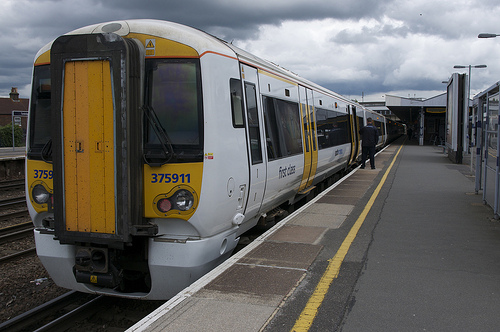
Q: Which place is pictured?
A: It is a station.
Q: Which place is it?
A: It is a station.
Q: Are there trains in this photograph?
A: Yes, there is a train.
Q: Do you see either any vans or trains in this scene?
A: Yes, there is a train.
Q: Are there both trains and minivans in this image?
A: No, there is a train but no minivans.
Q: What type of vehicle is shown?
A: The vehicle is a train.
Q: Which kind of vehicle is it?
A: The vehicle is a train.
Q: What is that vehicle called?
A: This is a train.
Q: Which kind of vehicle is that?
A: This is a train.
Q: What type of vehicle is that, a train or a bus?
A: This is a train.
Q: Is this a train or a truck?
A: This is a train.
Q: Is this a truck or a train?
A: This is a train.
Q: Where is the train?
A: The train is at the station.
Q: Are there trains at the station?
A: Yes, there is a train at the station.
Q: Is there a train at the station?
A: Yes, there is a train at the station.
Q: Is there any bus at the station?
A: No, there is a train at the station.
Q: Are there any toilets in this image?
A: No, there are no toilets.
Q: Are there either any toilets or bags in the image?
A: No, there are no toilets or bags.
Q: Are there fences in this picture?
A: No, there are no fences.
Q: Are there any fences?
A: No, there are no fences.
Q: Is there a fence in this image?
A: No, there are no fences.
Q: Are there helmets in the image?
A: No, there are no helmets.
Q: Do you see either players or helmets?
A: No, there are no helmets or players.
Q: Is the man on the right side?
A: Yes, the man is on the right of the image.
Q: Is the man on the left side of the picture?
A: No, the man is on the right of the image.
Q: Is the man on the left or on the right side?
A: The man is on the right of the image.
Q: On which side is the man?
A: The man is on the right of the image.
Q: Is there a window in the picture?
A: Yes, there is a window.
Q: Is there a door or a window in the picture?
A: Yes, there is a window.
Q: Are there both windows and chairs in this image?
A: No, there is a window but no chairs.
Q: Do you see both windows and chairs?
A: No, there is a window but no chairs.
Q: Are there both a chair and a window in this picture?
A: No, there is a window but no chairs.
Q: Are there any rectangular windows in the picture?
A: Yes, there is a rectangular window.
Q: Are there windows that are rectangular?
A: Yes, there is a window that is rectangular.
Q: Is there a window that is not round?
A: Yes, there is a rectangular window.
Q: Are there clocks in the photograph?
A: No, there are no clocks.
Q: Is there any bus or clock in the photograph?
A: No, there are no clocks or buses.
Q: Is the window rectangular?
A: Yes, the window is rectangular.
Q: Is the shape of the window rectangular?
A: Yes, the window is rectangular.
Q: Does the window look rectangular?
A: Yes, the window is rectangular.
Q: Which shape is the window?
A: The window is rectangular.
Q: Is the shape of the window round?
A: No, the window is rectangular.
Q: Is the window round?
A: No, the window is rectangular.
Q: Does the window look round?
A: No, the window is rectangular.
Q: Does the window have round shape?
A: No, the window is rectangular.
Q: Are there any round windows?
A: No, there is a window but it is rectangular.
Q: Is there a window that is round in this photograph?
A: No, there is a window but it is rectangular.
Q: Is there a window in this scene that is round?
A: No, there is a window but it is rectangular.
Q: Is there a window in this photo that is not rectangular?
A: No, there is a window but it is rectangular.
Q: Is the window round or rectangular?
A: The window is rectangular.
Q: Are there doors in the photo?
A: Yes, there is a door.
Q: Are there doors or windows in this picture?
A: Yes, there is a door.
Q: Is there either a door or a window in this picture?
A: Yes, there is a door.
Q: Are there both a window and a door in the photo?
A: Yes, there are both a door and a window.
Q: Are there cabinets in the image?
A: No, there are no cabinets.